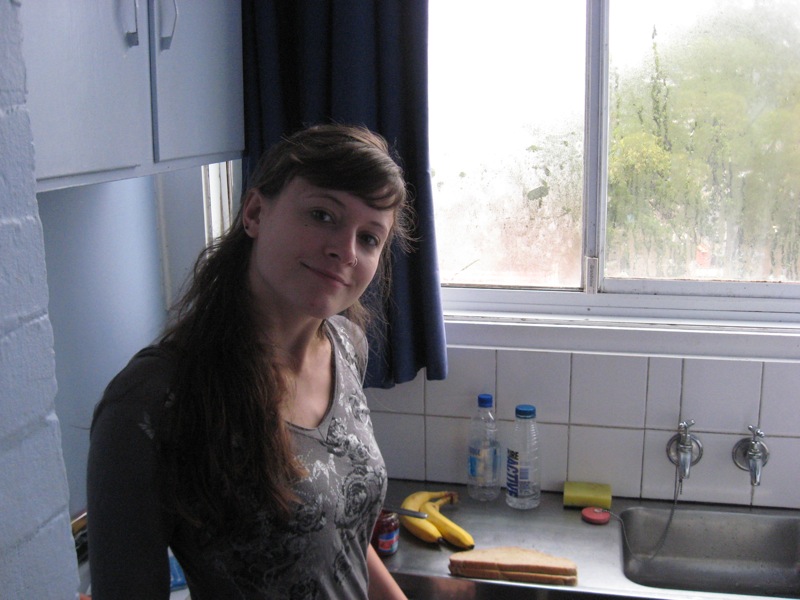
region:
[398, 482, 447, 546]
yellow banana on the black counter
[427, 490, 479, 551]
yellow banana on the black counter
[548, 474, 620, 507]
sponge on the black counter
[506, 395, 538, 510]
bottle on the black counter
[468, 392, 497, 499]
bottle on the black counter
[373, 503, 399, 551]
jar on the black counter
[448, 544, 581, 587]
bread on the black counter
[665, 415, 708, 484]
faucet on the white tile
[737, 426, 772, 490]
faucet on the white tile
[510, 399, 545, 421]
blue cap on the bottle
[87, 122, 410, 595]
woman has long hair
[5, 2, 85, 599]
bricks are painted white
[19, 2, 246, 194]
cabinet doors are painted white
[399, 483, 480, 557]
bananas are yellow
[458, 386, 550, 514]
two bottles are empty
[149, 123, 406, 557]
woman's hair hangs over her shoulder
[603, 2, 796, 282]
window is not completly clear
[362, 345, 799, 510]
tiles are white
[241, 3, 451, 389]
curtain is pulled back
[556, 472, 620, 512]
sponge rests on countertop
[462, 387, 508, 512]
a clear bottle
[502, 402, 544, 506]
a bottle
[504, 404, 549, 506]
the bottle is clear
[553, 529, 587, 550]
a counter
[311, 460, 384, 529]
a design on the shirt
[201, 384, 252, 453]
the womens hair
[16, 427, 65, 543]
a brick wall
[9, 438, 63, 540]
the brick wall is white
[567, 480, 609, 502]
the sponge is yellow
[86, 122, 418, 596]
woman stands in kitchen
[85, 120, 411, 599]
woman stands next to counter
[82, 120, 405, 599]
woman stands near sink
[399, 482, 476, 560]
bananas rest on counter top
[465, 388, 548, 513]
two bottles have their lids on them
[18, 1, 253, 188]
cabinet doors are shut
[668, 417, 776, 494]
faucets are turned off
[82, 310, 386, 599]
woman's shirt is grey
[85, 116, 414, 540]
hair is long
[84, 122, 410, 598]
Smiling woman standing in the kitchen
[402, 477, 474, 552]
Two bananas on the counter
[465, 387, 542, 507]
Two empty plastic bottles on the counter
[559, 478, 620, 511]
A yellow sponge near the sink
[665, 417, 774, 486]
Two faucets over the sink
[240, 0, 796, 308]
A window on the back wall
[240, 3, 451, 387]
Dark curtain over part of the window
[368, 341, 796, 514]
Tile backsplash under the window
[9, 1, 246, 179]
White cabinets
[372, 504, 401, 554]
Jar of food on the counter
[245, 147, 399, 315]
person has a head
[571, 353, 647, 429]
white tile is square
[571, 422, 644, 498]
white tile is square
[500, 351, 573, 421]
white tile is square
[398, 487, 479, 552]
two bananas laying on countertop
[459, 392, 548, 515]
two clear beverage bottles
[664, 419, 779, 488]
water faucets affixed to wall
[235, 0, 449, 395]
dark drape covering part of window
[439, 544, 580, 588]
sandwich-looking object sitting on counter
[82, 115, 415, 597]
woman posing for camera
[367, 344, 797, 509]
tiles lining wall behind sink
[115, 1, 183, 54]
silver handles on cupboard doors